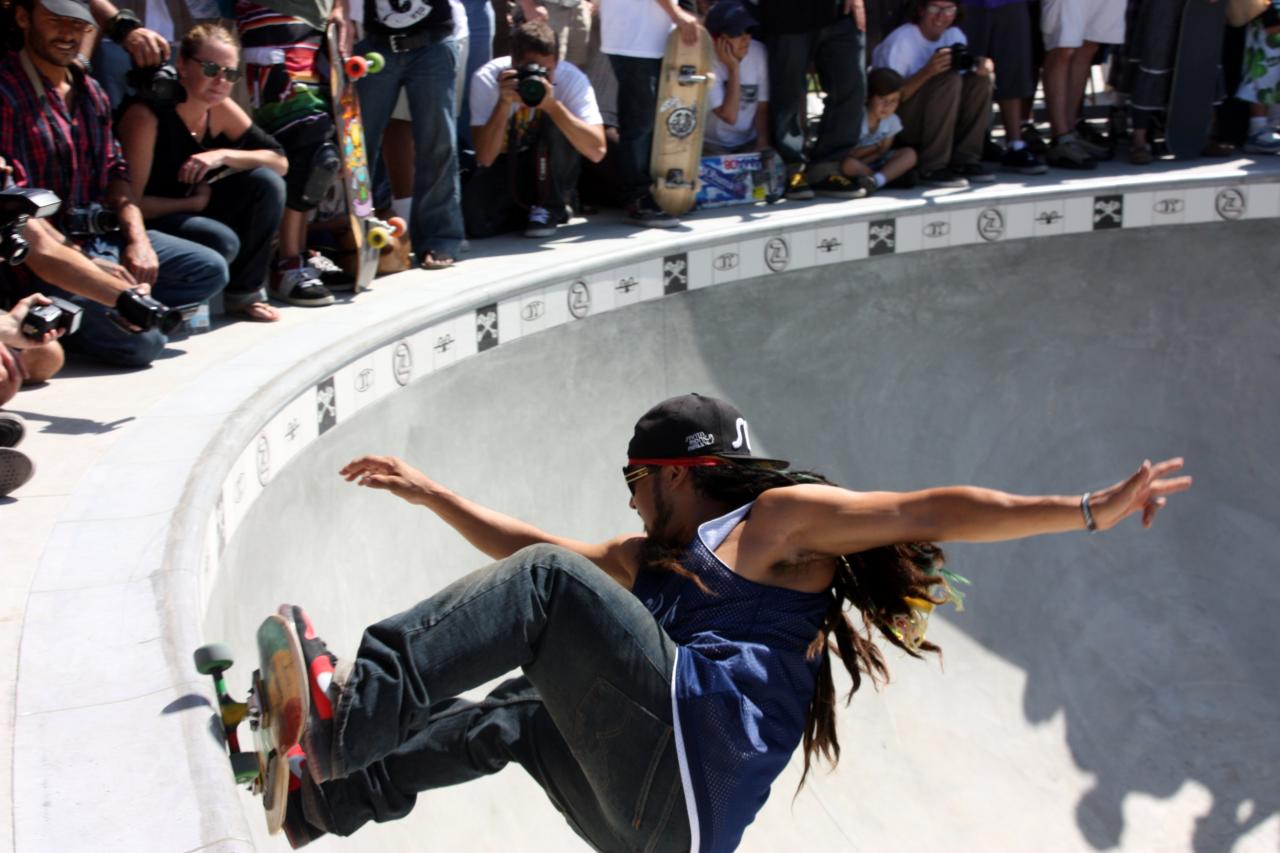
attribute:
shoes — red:
[247, 598, 342, 849]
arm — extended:
[748, 449, 1197, 558]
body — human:
[280, 388, 1196, 848]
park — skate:
[7, 146, 1240, 848]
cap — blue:
[631, 408, 817, 468]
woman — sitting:
[110, 25, 296, 329]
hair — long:
[762, 459, 969, 742]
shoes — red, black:
[229, 587, 357, 847]